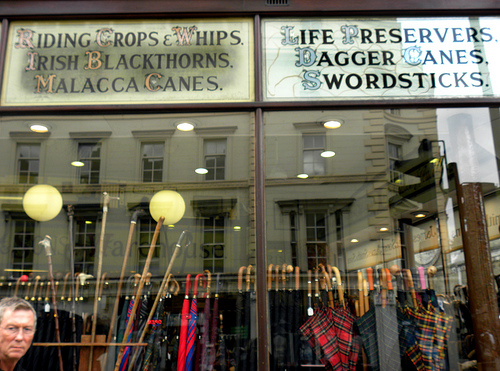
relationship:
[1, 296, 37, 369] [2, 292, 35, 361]
head on man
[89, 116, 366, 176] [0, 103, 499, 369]
lighting in store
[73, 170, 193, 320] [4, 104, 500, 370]
canes in store window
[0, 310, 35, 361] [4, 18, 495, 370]
face near store window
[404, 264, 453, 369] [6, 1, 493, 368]
umbrella inside store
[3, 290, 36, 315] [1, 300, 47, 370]
hair on head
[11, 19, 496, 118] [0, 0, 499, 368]
sign on building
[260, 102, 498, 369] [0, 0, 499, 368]
reflection on building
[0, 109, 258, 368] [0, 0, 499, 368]
reflection on building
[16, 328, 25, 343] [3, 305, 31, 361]
nose on face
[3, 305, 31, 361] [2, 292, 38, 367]
face of man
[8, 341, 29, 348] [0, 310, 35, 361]
mouth on face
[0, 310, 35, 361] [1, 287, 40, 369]
face of man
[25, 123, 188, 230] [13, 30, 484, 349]
light fixture illuminating store